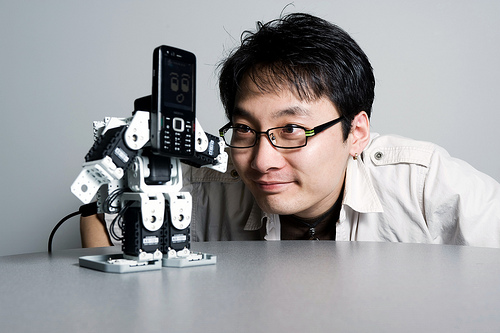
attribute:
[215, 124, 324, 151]
glasses — black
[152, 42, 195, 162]
mobile phone — old, black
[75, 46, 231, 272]
robot — small, black, white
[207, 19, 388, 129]
hair — black, short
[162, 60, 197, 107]
display — face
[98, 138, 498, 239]
jacket — white, light colored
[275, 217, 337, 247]
shirt — brown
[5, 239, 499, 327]
table — gray